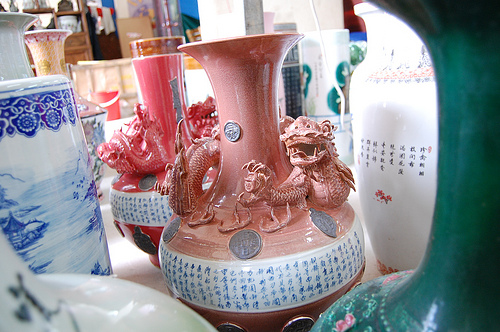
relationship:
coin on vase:
[222, 121, 242, 143] [160, 33, 365, 330]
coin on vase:
[308, 207, 339, 236] [310, 1, 497, 328]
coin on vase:
[228, 228, 263, 258] [95, 49, 217, 269]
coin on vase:
[160, 216, 182, 241] [22, 29, 72, 76]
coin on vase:
[217, 321, 238, 329] [160, 33, 365, 330]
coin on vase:
[228, 228, 263, 260] [138, 43, 353, 330]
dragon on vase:
[236, 115, 356, 210] [160, 33, 365, 330]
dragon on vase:
[161, 115, 359, 224] [160, 33, 365, 330]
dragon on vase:
[236, 115, 358, 211] [107, 40, 367, 327]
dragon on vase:
[154, 116, 356, 218] [107, 40, 367, 327]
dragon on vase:
[95, 96, 221, 176] [107, 40, 367, 327]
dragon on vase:
[107, 122, 174, 176] [126, 57, 199, 159]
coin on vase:
[228, 228, 263, 260] [153, 31, 377, 323]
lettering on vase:
[155, 223, 369, 318] [160, 33, 365, 330]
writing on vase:
[356, 137, 431, 176] [348, 0, 438, 275]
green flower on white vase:
[300, 62, 314, 96] [297, 26, 352, 156]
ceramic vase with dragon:
[156, 32, 365, 331] [154, 116, 356, 218]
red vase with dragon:
[94, 32, 222, 269] [95, 96, 221, 176]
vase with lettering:
[68, 56, 399, 290] [149, 230, 369, 315]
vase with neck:
[105, 46, 217, 273] [132, 55, 189, 134]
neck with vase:
[173, 30, 309, 207] [116, 24, 406, 326]